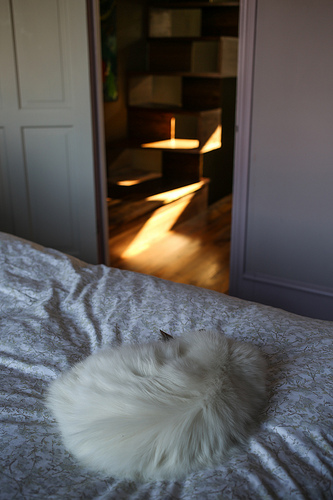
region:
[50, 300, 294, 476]
a cat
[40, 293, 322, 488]
a white cat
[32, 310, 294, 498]
a white cat with long fur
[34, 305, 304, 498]
a white cat sleeping on a bed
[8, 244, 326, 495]
the bed has sheets on it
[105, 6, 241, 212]
boxes stacked up in a room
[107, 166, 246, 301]
the room has a wood floor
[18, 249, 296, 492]
the bedspread is white with a pattern on it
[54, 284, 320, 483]
the cat is curled in a ball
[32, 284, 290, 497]
a fluffy cat is sleeping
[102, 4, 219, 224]
Wooden series of platforms and cubby holes.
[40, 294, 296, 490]
White cat curled up.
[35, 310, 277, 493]
Sleeping white cat.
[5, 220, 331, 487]
Bed with floral patterned comforter.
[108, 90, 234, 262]
Sunlight shining on wooden floor.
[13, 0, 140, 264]
White door.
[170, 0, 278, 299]
Lavender door jamb.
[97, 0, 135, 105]
Green poster hanging on a wall.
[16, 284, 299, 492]
Animal making an indentation on a bed.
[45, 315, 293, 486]
White cat with brown ears.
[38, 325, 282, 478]
white sleeping cat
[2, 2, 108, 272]
white panel door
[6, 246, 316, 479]
cat sleeping on a bed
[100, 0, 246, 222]
shelves in the background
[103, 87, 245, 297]
sun shining in the back room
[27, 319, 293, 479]
white cat with dark colored ears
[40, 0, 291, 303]
open doorway into another room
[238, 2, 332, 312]
gray walls with lavender trim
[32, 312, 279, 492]
long haired cat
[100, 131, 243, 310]
hardwood floors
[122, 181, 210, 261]
Light reflecting in a dark room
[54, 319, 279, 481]
White fluffy cat sleeping on bed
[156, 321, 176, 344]
Ear of a white fluffy cat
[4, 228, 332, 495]
A bed sheet with a unique pattern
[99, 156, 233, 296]
Red hardwood floor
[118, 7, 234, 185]
Multiple drawers in the backroom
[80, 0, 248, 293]
Doorway entrance into the room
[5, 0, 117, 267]
White door opened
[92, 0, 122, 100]
Green poser in the room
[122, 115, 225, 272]
Yellow light reflected on the red hardwood floor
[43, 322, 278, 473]
white ball of fur on bed